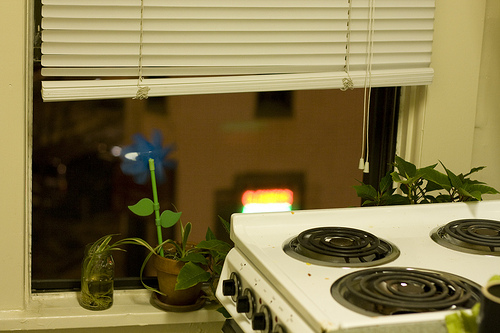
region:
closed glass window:
[26, 0, 396, 294]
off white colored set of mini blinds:
[33, 1, 436, 98]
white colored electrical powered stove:
[211, 190, 498, 327]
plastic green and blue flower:
[117, 138, 182, 255]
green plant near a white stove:
[355, 153, 495, 210]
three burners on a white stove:
[283, 212, 498, 314]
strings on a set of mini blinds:
[358, 85, 374, 177]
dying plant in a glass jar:
[78, 228, 159, 312]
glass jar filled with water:
[77, 252, 118, 311]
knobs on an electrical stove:
[220, 270, 287, 331]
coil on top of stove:
[287, 217, 392, 266]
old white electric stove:
[220, 178, 494, 329]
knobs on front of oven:
[217, 262, 280, 327]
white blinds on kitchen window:
[32, 11, 447, 113]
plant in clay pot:
[137, 231, 233, 316]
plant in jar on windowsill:
[72, 239, 134, 318]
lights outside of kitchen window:
[232, 168, 318, 218]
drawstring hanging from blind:
[354, 84, 381, 179]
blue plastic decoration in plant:
[109, 119, 186, 186]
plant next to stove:
[355, 154, 495, 209]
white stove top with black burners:
[255, 177, 495, 324]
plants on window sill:
[68, 223, 220, 311]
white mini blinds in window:
[42, 5, 441, 117]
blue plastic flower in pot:
[122, 121, 194, 262]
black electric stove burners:
[297, 217, 386, 265]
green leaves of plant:
[355, 169, 499, 209]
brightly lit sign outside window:
[224, 172, 303, 218]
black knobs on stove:
[220, 265, 265, 312]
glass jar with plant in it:
[78, 227, 129, 312]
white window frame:
[3, 3, 63, 330]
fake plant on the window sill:
[119, 136, 180, 254]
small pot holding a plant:
[148, 235, 215, 308]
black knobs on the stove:
[214, 261, 291, 331]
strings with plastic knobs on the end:
[355, 76, 387, 176]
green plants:
[349, 147, 498, 208]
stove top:
[234, 200, 493, 317]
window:
[9, 3, 431, 310]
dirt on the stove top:
[289, 242, 343, 292]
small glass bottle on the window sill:
[66, 241, 143, 319]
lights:
[231, 176, 301, 213]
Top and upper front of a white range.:
[217, 200, 498, 330]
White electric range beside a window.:
[215, 199, 496, 329]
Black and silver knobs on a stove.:
[215, 270, 295, 330]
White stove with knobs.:
[210, 270, 295, 330]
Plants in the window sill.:
[60, 225, 215, 316]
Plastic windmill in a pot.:
[120, 126, 180, 306]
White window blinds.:
[35, 0, 436, 100]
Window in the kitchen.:
[1, 0, 482, 327]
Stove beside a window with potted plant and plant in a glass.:
[10, 5, 480, 317]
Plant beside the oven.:
[351, 151, 494, 202]